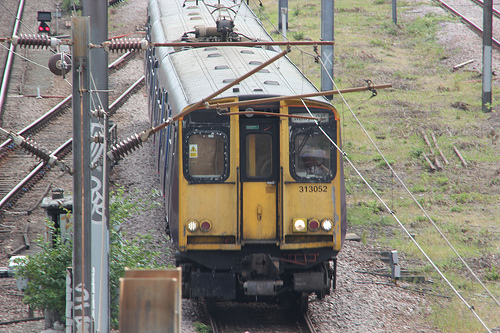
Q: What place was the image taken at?
A: It was taken at the field.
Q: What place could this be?
A: It is a field.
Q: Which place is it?
A: It is a field.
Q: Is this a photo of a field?
A: Yes, it is showing a field.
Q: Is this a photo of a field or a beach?
A: It is showing a field.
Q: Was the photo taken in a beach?
A: No, the picture was taken in a field.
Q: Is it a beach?
A: No, it is a field.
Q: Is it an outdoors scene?
A: Yes, it is outdoors.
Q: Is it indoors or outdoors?
A: It is outdoors.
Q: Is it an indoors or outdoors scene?
A: It is outdoors.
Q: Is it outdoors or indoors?
A: It is outdoors.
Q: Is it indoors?
A: No, it is outdoors.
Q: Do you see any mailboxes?
A: No, there are no mailboxes.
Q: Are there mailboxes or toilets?
A: No, there are no mailboxes or toilets.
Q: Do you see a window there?
A: Yes, there is a window.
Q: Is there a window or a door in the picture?
A: Yes, there is a window.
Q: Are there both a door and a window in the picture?
A: Yes, there are both a window and a door.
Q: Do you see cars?
A: No, there are no cars.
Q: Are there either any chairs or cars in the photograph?
A: No, there are no cars or chairs.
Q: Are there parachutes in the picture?
A: No, there are no parachutes.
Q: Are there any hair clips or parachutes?
A: No, there are no parachutes or hair clips.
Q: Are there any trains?
A: Yes, there is a train.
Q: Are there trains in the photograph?
A: Yes, there is a train.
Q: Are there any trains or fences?
A: Yes, there is a train.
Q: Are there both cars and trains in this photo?
A: No, there is a train but no cars.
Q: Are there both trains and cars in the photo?
A: No, there is a train but no cars.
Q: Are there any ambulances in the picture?
A: No, there are no ambulances.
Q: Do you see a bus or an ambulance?
A: No, there are no ambulances or buses.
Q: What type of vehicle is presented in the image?
A: The vehicle is a train.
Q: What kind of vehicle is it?
A: The vehicle is a train.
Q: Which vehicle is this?
A: That is a train.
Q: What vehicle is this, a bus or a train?
A: That is a train.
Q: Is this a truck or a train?
A: This is a train.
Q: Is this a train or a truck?
A: This is a train.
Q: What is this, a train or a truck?
A: This is a train.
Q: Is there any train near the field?
A: Yes, there is a train near the field.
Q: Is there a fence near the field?
A: No, there is a train near the field.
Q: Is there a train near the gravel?
A: Yes, there is a train near the gravel.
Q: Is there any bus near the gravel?
A: No, there is a train near the gravel.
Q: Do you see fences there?
A: No, there are no fences.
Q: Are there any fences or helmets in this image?
A: No, there are no fences or helmets.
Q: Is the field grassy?
A: Yes, the field is grassy.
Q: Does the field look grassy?
A: Yes, the field is grassy.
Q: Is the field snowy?
A: No, the field is grassy.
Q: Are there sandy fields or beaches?
A: No, there is a field but it is grassy.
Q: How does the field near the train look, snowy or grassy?
A: The field is grassy.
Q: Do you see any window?
A: Yes, there is a window.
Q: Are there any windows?
A: Yes, there is a window.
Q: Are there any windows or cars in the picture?
A: Yes, there is a window.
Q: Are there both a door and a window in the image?
A: Yes, there are both a window and a door.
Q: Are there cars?
A: No, there are no cars.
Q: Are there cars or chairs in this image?
A: No, there are no cars or chairs.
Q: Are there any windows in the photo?
A: Yes, there are windows.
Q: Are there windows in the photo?
A: Yes, there are windows.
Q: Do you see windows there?
A: Yes, there are windows.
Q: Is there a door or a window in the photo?
A: Yes, there are windows.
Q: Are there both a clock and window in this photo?
A: No, there are windows but no clocks.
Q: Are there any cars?
A: No, there are no cars.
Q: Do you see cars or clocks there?
A: No, there are no cars or clocks.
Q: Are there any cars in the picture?
A: No, there are no cars.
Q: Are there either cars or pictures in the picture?
A: No, there are no cars or pictures.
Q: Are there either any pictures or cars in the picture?
A: No, there are no cars or pictures.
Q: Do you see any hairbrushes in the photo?
A: No, there are no hairbrushes.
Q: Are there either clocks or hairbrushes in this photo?
A: No, there are no hairbrushes or clocks.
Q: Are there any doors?
A: Yes, there is a door.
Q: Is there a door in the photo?
A: Yes, there is a door.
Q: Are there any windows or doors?
A: Yes, there is a door.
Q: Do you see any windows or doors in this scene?
A: Yes, there is a door.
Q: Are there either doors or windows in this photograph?
A: Yes, there is a door.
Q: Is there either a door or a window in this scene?
A: Yes, there is a door.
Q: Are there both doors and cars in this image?
A: No, there is a door but no cars.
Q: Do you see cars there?
A: No, there are no cars.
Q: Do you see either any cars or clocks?
A: No, there are no cars or clocks.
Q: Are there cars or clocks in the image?
A: No, there are no cars or clocks.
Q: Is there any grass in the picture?
A: Yes, there is grass.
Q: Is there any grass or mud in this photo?
A: Yes, there is grass.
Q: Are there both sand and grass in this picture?
A: No, there is grass but no sand.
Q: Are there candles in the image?
A: No, there are no candles.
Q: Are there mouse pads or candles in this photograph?
A: No, there are no candles or mouse pads.